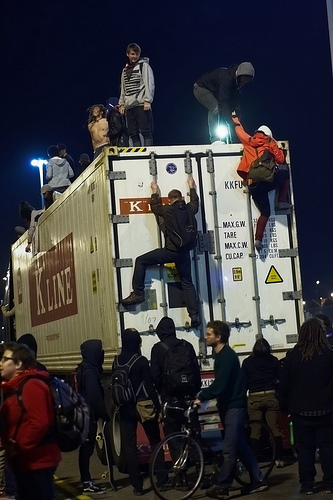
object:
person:
[118, 42, 156, 148]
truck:
[1, 139, 305, 477]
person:
[193, 61, 255, 144]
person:
[85, 103, 110, 162]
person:
[45, 145, 75, 195]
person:
[240, 336, 286, 468]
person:
[278, 317, 333, 496]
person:
[149, 315, 214, 492]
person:
[110, 327, 170, 498]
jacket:
[0, 362, 63, 472]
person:
[0, 340, 62, 500]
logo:
[29, 231, 78, 327]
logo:
[120, 196, 184, 215]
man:
[193, 320, 271, 500]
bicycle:
[149, 399, 278, 500]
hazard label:
[264, 265, 283, 284]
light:
[31, 158, 49, 167]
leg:
[23, 208, 42, 254]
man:
[231, 111, 292, 252]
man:
[121, 173, 201, 327]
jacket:
[231, 116, 286, 182]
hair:
[125, 42, 141, 55]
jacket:
[194, 65, 242, 123]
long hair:
[85, 103, 108, 125]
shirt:
[74, 160, 90, 180]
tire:
[149, 431, 206, 500]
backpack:
[164, 199, 200, 252]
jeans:
[214, 406, 266, 490]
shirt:
[117, 56, 155, 111]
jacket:
[75, 338, 112, 424]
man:
[70, 338, 111, 497]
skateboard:
[95, 419, 118, 491]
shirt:
[197, 344, 248, 410]